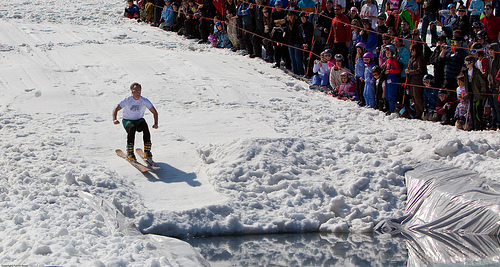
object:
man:
[112, 83, 158, 161]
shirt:
[117, 96, 152, 120]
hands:
[152, 123, 160, 131]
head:
[130, 83, 144, 98]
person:
[373, 67, 382, 111]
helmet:
[362, 53, 373, 60]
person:
[337, 71, 357, 101]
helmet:
[355, 41, 367, 50]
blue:
[369, 90, 370, 91]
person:
[385, 46, 401, 114]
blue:
[391, 90, 392, 91]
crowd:
[343, 1, 496, 130]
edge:
[194, 233, 396, 234]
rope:
[325, 16, 355, 25]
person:
[328, 5, 351, 57]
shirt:
[324, 15, 350, 46]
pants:
[386, 72, 399, 117]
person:
[410, 44, 424, 120]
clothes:
[407, 57, 421, 118]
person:
[356, 19, 379, 55]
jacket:
[359, 29, 378, 50]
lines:
[32, 49, 49, 97]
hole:
[135, 227, 238, 254]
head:
[361, 55, 376, 63]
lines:
[305, 0, 318, 80]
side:
[207, 0, 499, 208]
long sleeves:
[325, 22, 333, 44]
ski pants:
[124, 118, 152, 161]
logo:
[129, 104, 141, 111]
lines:
[126, 143, 135, 153]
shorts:
[121, 119, 151, 132]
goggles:
[133, 87, 144, 93]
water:
[291, 250, 352, 258]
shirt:
[385, 56, 403, 74]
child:
[359, 52, 377, 106]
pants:
[243, 25, 258, 53]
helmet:
[384, 44, 396, 50]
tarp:
[407, 158, 500, 235]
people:
[459, 48, 488, 128]